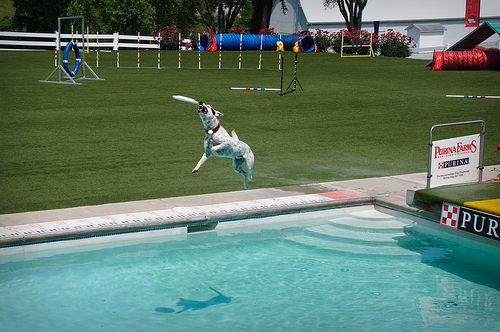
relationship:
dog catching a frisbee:
[191, 100, 257, 190] [164, 88, 204, 113]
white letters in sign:
[457, 209, 497, 241] [425, 200, 484, 260]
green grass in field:
[1, 51, 498, 213] [0, 45, 498, 215]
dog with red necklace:
[191, 100, 257, 190] [204, 125, 221, 137]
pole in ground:
[249, 30, 266, 82] [2, 48, 471, 218]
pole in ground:
[232, 31, 246, 68] [189, 56, 302, 101]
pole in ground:
[194, 31, 207, 71] [2, 48, 471, 218]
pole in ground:
[92, 24, 182, 101] [2, 48, 471, 218]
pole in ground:
[131, 30, 145, 65] [0, 46, 477, 192]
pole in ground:
[444, 92, 499, 98] [309, 98, 496, 122]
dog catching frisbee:
[191, 102, 256, 184] [169, 90, 198, 111]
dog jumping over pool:
[191, 100, 257, 190] [2, 207, 499, 329]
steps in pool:
[286, 202, 438, 264] [2, 207, 499, 329]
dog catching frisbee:
[191, 100, 257, 190] [171, 90, 203, 105]